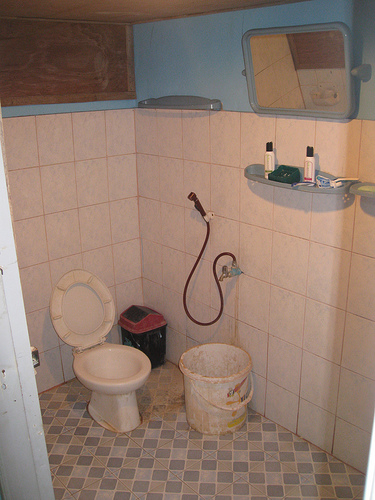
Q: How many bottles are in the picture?
A: Two.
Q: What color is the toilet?
A: White.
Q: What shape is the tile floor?
A: Diamonds.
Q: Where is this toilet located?
A: In a bathroom.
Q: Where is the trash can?
A: In the corner.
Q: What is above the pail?
A: A hose.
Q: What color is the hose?
A: Red.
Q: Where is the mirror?
A: On the wall.